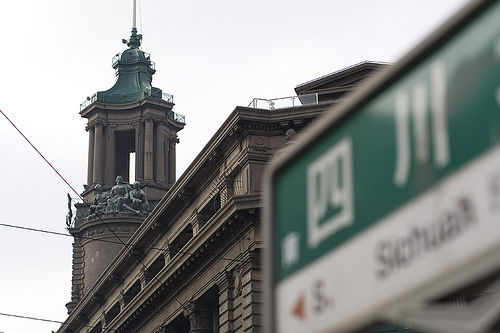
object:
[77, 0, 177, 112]
roof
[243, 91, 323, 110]
fence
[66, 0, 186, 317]
tower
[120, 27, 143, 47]
statue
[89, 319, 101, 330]
window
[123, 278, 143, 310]
window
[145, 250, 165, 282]
window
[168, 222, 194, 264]
window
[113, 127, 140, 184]
window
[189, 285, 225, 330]
window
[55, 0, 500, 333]
building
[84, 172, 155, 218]
statue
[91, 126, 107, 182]
pillars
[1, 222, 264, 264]
line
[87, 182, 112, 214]
man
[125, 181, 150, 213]
woman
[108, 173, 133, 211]
man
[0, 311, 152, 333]
wires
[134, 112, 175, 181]
columns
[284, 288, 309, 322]
arrow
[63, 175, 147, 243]
deck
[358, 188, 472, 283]
word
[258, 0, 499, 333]
sign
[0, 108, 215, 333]
cables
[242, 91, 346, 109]
railing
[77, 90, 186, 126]
railing